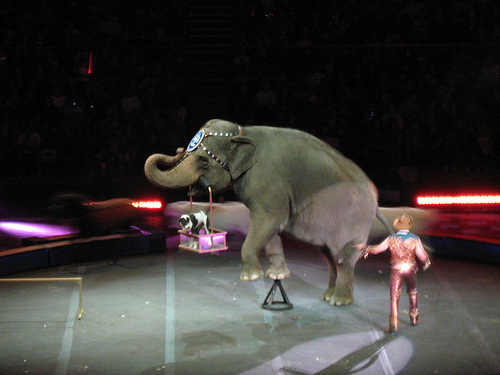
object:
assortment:
[109, 301, 137, 327]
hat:
[391, 213, 415, 231]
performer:
[352, 213, 433, 335]